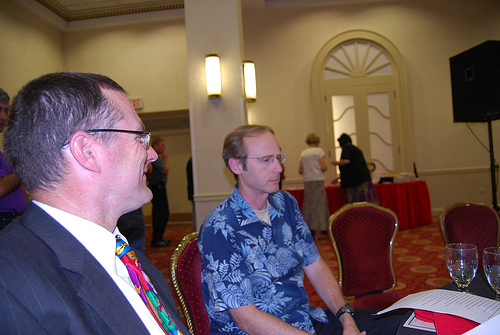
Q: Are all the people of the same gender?
A: No, they are both male and female.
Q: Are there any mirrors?
A: No, there are no mirrors.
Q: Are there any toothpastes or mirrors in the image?
A: No, there are no mirrors or toothpastes.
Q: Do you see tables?
A: Yes, there is a table.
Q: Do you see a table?
A: Yes, there is a table.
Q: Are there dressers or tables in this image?
A: Yes, there is a table.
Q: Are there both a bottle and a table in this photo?
A: No, there is a table but no bottles.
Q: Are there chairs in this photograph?
A: Yes, there is a chair.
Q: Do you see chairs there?
A: Yes, there is a chair.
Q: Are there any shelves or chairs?
A: Yes, there is a chair.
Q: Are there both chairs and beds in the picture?
A: No, there is a chair but no beds.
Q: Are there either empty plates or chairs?
A: Yes, there is an empty chair.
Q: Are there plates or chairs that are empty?
A: Yes, the chair is empty.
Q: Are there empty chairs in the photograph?
A: Yes, there is an empty chair.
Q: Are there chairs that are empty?
A: Yes, there is a chair that is empty.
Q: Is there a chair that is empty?
A: Yes, there is a chair that is empty.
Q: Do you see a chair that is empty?
A: Yes, there is a chair that is empty.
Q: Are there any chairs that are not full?
A: Yes, there is a empty chair.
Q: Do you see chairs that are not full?
A: Yes, there is a empty chair.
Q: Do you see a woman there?
A: Yes, there is a woman.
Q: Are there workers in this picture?
A: No, there are no workers.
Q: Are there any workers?
A: No, there are no workers.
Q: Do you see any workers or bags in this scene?
A: No, there are no workers or bags.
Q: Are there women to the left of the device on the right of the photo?
A: Yes, there is a woman to the left of the speaker.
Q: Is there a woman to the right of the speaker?
A: No, the woman is to the left of the speaker.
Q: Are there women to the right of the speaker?
A: No, the woman is to the left of the speaker.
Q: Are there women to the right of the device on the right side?
A: No, the woman is to the left of the speaker.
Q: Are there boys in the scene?
A: No, there are no boys.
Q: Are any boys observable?
A: No, there are no boys.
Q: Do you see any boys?
A: No, there are no boys.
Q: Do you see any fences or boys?
A: No, there are no boys or fences.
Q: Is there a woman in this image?
A: Yes, there is a woman.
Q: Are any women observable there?
A: Yes, there is a woman.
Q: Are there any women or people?
A: Yes, there is a woman.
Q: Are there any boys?
A: No, there are no boys.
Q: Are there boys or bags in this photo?
A: No, there are no boys or bags.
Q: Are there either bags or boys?
A: No, there are no boys or bags.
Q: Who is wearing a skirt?
A: The woman is wearing a skirt.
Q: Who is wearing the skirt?
A: The woman is wearing a skirt.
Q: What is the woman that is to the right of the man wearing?
A: The woman is wearing a skirt.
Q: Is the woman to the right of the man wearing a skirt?
A: Yes, the woman is wearing a skirt.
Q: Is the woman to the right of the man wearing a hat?
A: No, the woman is wearing a skirt.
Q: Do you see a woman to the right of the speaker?
A: No, the woman is to the left of the speaker.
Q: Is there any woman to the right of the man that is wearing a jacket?
A: Yes, there is a woman to the right of the man.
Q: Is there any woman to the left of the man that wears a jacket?
A: No, the woman is to the right of the man.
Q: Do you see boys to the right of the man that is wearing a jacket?
A: No, there is a woman to the right of the man.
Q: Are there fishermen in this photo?
A: No, there are no fishermen.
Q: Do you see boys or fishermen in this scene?
A: No, there are no fishermen or boys.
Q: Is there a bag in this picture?
A: No, there are no bags.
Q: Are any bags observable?
A: No, there are no bags.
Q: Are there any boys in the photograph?
A: No, there are no boys.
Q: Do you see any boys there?
A: No, there are no boys.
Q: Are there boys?
A: No, there are no boys.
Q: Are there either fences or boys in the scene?
A: No, there are no boys or fences.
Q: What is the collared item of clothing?
A: The clothing item is a shirt.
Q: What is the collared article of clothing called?
A: The clothing item is a shirt.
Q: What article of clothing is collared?
A: The clothing item is a shirt.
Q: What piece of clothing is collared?
A: The clothing item is a shirt.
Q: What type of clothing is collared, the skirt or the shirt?
A: The shirt is collared.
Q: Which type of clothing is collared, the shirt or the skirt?
A: The shirt is collared.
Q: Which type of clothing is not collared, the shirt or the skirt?
A: The skirt is not collared.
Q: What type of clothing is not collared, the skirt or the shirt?
A: The skirt is not collared.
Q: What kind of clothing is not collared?
A: The clothing is a skirt.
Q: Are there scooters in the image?
A: No, there are no scooters.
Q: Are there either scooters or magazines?
A: No, there are no scooters or magazines.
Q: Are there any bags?
A: No, there are no bags.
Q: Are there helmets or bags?
A: No, there are no bags or helmets.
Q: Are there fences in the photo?
A: No, there are no fences.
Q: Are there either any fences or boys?
A: No, there are no fences or boys.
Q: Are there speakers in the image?
A: Yes, there is a speaker.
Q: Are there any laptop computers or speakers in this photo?
A: Yes, there is a speaker.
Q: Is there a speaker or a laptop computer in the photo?
A: Yes, there is a speaker.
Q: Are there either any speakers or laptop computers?
A: Yes, there is a speaker.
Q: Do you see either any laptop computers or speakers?
A: Yes, there is a speaker.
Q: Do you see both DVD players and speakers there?
A: No, there is a speaker but no DVD players.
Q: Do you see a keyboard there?
A: No, there are no keyboards.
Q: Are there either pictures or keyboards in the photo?
A: No, there are no keyboards or pictures.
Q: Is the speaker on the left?
A: No, the speaker is on the right of the image.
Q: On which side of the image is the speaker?
A: The speaker is on the right of the image.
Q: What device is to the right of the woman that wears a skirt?
A: The device is a speaker.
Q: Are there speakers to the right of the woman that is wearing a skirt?
A: Yes, there is a speaker to the right of the woman.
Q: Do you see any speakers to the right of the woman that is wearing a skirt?
A: Yes, there is a speaker to the right of the woman.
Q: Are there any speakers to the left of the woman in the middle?
A: No, the speaker is to the right of the woman.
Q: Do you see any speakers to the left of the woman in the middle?
A: No, the speaker is to the right of the woman.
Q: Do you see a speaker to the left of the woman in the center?
A: No, the speaker is to the right of the woman.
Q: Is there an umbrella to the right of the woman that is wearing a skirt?
A: No, there is a speaker to the right of the woman.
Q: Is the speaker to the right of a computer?
A: No, the speaker is to the right of the woman.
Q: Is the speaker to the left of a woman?
A: No, the speaker is to the right of a woman.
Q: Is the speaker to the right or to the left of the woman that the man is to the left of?
A: The speaker is to the right of the woman.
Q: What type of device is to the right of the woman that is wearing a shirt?
A: The device is a speaker.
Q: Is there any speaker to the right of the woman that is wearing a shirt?
A: Yes, there is a speaker to the right of the woman.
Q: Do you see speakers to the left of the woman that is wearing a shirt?
A: No, the speaker is to the right of the woman.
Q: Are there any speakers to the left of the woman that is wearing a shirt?
A: No, the speaker is to the right of the woman.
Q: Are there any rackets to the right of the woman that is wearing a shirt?
A: No, there is a speaker to the right of the woman.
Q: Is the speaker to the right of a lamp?
A: No, the speaker is to the right of the woman.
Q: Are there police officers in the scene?
A: No, there are no police officers.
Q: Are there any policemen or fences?
A: No, there are no policemen or fences.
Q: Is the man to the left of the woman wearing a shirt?
A: Yes, the man is wearing a shirt.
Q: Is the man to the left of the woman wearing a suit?
A: No, the man is wearing a shirt.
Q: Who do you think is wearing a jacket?
A: The man is wearing a jacket.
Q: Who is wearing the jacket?
A: The man is wearing a jacket.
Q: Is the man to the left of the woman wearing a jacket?
A: Yes, the man is wearing a jacket.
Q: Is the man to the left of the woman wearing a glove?
A: No, the man is wearing a jacket.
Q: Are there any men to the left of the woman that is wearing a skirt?
A: Yes, there is a man to the left of the woman.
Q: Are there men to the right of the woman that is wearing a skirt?
A: No, the man is to the left of the woman.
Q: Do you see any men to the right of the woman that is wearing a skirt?
A: No, the man is to the left of the woman.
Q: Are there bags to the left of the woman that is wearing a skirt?
A: No, there is a man to the left of the woman.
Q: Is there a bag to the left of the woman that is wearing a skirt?
A: No, there is a man to the left of the woman.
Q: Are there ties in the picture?
A: Yes, there is a tie.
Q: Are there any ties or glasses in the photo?
A: Yes, there is a tie.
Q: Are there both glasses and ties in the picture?
A: Yes, there are both a tie and glasses.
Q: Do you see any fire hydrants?
A: No, there are no fire hydrants.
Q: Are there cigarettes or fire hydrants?
A: No, there are no fire hydrants or cigarettes.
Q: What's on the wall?
A: The sconce is on the wall.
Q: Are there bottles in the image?
A: No, there are no bottles.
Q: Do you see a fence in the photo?
A: No, there are no fences.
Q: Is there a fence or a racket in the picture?
A: No, there are no fences or rackets.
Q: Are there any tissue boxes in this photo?
A: No, there are no tissue boxes.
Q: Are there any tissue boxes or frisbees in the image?
A: No, there are no tissue boxes or frisbees.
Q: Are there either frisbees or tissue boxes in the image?
A: No, there are no tissue boxes or frisbees.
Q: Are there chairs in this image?
A: Yes, there is a chair.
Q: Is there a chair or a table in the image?
A: Yes, there is a chair.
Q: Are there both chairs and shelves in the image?
A: No, there is a chair but no shelves.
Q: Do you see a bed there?
A: No, there are no beds.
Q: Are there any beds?
A: No, there are no beds.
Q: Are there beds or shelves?
A: No, there are no beds or shelves.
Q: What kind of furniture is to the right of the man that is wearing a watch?
A: The piece of furniture is a chair.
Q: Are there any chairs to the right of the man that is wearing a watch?
A: Yes, there is a chair to the right of the man.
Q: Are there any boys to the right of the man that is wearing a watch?
A: No, there is a chair to the right of the man.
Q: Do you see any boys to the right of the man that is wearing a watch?
A: No, there is a chair to the right of the man.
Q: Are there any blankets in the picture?
A: No, there are no blankets.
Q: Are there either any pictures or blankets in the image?
A: No, there are no blankets or pictures.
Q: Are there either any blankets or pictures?
A: No, there are no blankets or pictures.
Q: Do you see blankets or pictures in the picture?
A: No, there are no blankets or pictures.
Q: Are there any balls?
A: No, there are no balls.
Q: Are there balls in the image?
A: No, there are no balls.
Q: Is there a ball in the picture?
A: No, there are no balls.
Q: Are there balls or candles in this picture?
A: No, there are no balls or candles.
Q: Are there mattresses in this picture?
A: No, there are no mattresses.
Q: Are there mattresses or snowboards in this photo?
A: No, there are no mattresses or snowboards.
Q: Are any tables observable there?
A: Yes, there is a table.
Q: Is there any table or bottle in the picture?
A: Yes, there is a table.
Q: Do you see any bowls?
A: No, there are no bowls.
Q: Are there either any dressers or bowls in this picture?
A: No, there are no bowls or dressers.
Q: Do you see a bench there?
A: No, there are no benches.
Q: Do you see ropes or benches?
A: No, there are no benches or ropes.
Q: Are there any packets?
A: No, there are no packets.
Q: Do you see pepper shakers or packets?
A: No, there are no packets or pepper shakers.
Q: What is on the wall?
A: The sconce is on the wall.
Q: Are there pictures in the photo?
A: No, there are no pictures.